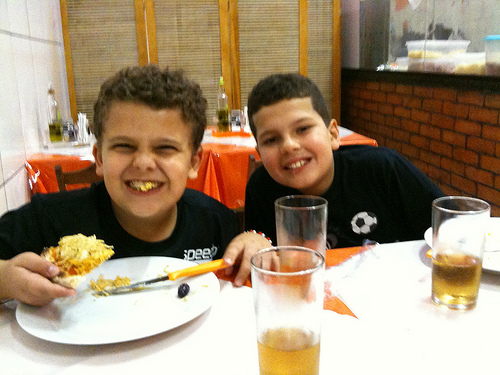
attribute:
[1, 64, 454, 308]
boys — people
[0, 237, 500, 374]
table — white, long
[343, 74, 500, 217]
wall — brown, brick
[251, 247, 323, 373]
glass — beverage, tall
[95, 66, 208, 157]
hair — brown, curly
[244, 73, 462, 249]
boy — smiling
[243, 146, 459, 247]
shirt — black, blue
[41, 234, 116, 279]
food — piece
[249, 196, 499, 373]
glasses — three, clear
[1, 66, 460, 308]
kids — sitting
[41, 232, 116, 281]
pizza — slice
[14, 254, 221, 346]
plate — white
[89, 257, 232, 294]
knife — yellow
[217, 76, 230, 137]
bottle — oil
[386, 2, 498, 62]
window — plastic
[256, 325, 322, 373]
juice — orange